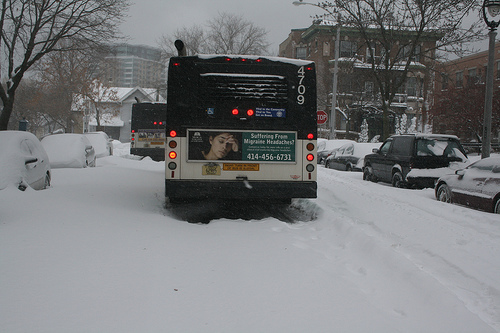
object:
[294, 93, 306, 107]
numbers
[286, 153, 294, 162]
numbers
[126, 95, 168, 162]
bus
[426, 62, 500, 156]
tree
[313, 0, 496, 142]
tree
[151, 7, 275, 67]
tree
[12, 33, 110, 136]
tree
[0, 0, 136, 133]
tree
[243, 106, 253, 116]
lights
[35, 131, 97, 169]
car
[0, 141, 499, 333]
snow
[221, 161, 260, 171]
license plate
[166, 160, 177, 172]
light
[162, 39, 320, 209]
bus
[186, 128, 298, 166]
sign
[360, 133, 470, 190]
car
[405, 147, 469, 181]
snow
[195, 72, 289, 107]
bus vent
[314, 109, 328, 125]
stop sign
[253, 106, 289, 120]
sign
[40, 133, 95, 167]
snow